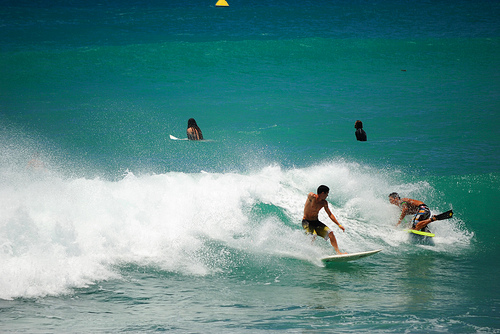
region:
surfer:
[262, 164, 376, 269]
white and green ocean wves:
[20, 171, 62, 226]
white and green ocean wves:
[385, 288, 416, 319]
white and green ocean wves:
[205, 249, 250, 289]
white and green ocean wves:
[108, 261, 159, 292]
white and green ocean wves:
[50, 236, 95, 261]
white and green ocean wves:
[60, 201, 105, 229]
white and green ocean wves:
[25, 161, 75, 212]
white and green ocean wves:
[54, 82, 71, 99]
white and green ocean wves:
[241, 16, 262, 48]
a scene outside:
[4, 2, 490, 332]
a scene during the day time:
[3, 3, 496, 332]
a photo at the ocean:
[5, 10, 497, 331]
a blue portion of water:
[1, 0, 497, 57]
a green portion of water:
[5, 34, 499, 178]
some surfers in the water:
[282, 165, 467, 272]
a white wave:
[0, 132, 483, 304]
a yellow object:
[207, 0, 245, 14]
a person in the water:
[338, 106, 377, 143]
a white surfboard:
[295, 238, 412, 278]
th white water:
[150, 187, 227, 262]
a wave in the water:
[123, 183, 204, 237]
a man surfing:
[296, 183, 353, 255]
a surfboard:
[323, 243, 383, 266]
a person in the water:
[184, 117, 210, 143]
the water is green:
[246, 84, 308, 134]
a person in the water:
[381, 194, 451, 247]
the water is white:
[161, 187, 218, 233]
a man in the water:
[347, 113, 371, 145]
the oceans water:
[252, 62, 329, 123]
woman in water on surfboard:
[159, 113, 222, 145]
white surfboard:
[165, 129, 214, 145]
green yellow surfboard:
[390, 222, 436, 249]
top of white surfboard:
[312, 245, 383, 269]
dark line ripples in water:
[217, 295, 331, 317]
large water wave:
[5, 147, 470, 302]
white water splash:
[7, 124, 95, 185]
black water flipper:
[427, 203, 459, 226]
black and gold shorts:
[297, 213, 335, 241]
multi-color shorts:
[406, 199, 433, 240]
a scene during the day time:
[7, 10, 469, 332]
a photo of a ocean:
[4, 0, 494, 321]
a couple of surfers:
[275, 170, 497, 289]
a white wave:
[16, 128, 491, 283]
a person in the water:
[305, 103, 436, 153]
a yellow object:
[205, 0, 230, 22]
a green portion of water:
[18, 53, 475, 170]